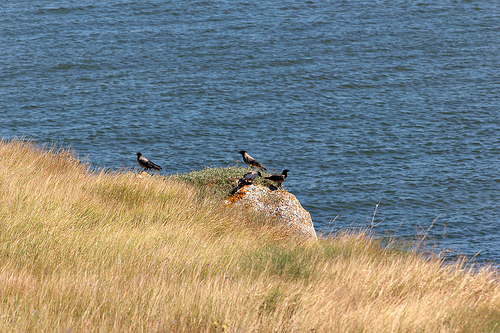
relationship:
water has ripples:
[2, 1, 498, 271] [238, 54, 321, 94]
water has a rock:
[2, 1, 498, 271] [164, 162, 322, 245]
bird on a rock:
[238, 149, 266, 172] [164, 162, 322, 245]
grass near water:
[0, 134, 499, 332] [2, 1, 498, 271]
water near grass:
[2, 1, 498, 271] [0, 134, 499, 332]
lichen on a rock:
[136, 150, 164, 175] [164, 162, 322, 245]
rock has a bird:
[164, 162, 322, 245] [238, 149, 266, 172]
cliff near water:
[164, 165, 322, 251] [2, 1, 498, 271]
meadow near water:
[2, 140, 499, 333] [2, 1, 498, 271]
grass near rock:
[0, 134, 499, 332] [164, 166, 318, 245]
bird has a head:
[238, 149, 266, 172] [237, 148, 248, 157]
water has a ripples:
[2, 1, 498, 271] [238, 54, 321, 94]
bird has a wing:
[238, 149, 266, 172] [248, 158, 265, 171]